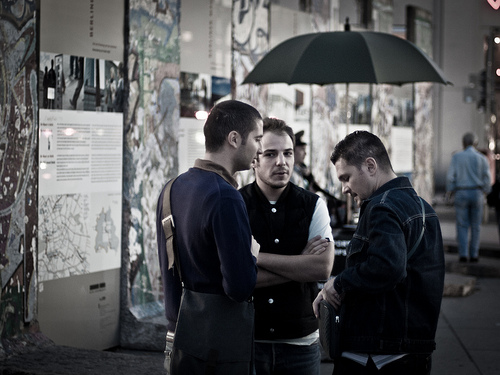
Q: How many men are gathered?
A: 3.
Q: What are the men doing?
A: Talking.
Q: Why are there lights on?
A: It is night time.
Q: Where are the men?
A: In front of a building.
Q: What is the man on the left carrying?
A: A bag.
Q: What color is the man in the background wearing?
A: Blue.